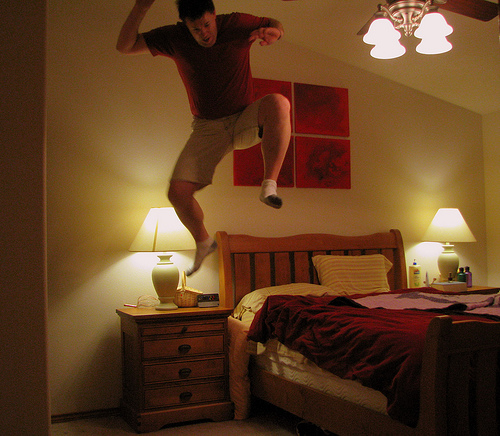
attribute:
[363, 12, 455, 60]
lights — on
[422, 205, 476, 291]
lamp — on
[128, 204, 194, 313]
lamp — on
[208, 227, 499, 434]
bed frame — wooden, unmade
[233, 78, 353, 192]
picture — red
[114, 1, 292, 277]
man — jumping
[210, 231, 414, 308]
headboard — wood, wooden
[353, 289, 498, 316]
blanket — rumpled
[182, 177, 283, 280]
socks — white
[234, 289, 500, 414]
mattress — white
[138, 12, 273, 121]
shirt — red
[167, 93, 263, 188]
shorts — khaki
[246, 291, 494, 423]
blanket — red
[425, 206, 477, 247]
shades — white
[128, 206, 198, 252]
shades — white